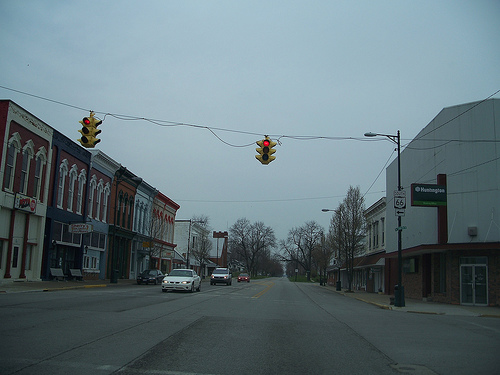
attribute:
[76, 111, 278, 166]
lights — stop, traffic, hanging, red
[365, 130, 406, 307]
lamp — black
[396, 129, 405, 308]
post — metal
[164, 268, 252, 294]
cars — three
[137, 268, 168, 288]
car — parked, moving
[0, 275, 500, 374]
road — black, tarmacked, clean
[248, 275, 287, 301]
lines — yellow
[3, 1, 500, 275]
skies — blue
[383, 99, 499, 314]
building — concrete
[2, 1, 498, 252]
sky — grey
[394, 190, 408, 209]
sign — black, arrow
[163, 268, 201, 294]
car — white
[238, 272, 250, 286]
car — red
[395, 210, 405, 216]
arrow — black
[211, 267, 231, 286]
suv — white